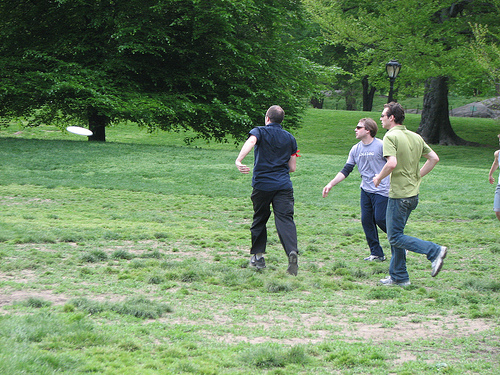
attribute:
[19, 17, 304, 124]
tree — large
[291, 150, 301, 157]
ribbon — red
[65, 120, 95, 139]
frisbee — white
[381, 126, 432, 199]
shirt — light, green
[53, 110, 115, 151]
frisbee — white, airborne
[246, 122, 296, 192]
shirt — dark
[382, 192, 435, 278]
pants — dark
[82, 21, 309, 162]
leaves — green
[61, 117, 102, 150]
frisbee — airborne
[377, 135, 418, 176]
shirt — green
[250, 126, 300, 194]
shirt — blue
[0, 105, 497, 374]
field — open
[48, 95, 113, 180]
frisbee — airborne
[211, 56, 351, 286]
man — running